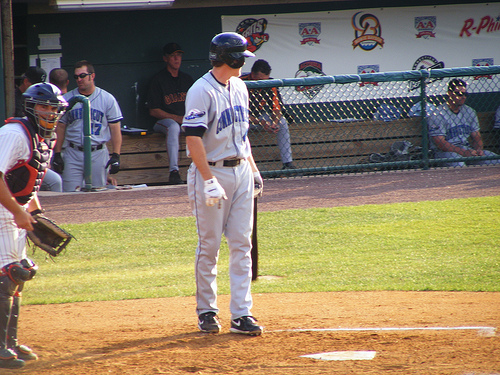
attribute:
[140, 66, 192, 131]
shirt — black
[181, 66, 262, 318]
uniform — gray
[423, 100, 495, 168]
uniform — gray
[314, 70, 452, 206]
fencing — green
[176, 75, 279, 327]
uniform — grey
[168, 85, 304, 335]
uniform — grey, blue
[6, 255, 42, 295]
padding — red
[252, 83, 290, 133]
shirt — black, orange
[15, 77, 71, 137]
batting helmet — black, plastic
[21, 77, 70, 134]
catchers helmet — plastic, black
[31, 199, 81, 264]
catchers mitt — brown, leather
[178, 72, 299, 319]
baseball uniform — blue, white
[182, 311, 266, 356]
white cleats — black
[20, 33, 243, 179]
rubber home plate — white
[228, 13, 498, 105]
banner — white